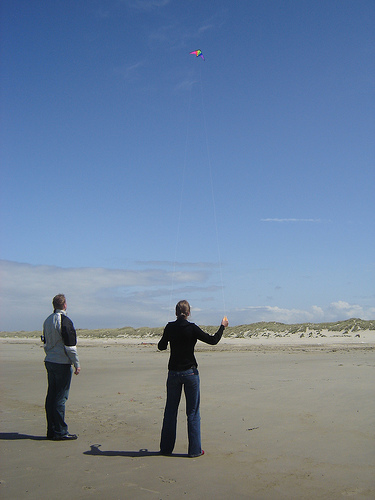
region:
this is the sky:
[43, 32, 104, 97]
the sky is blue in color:
[72, 163, 150, 204]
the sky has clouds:
[98, 264, 152, 309]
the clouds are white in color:
[102, 267, 144, 287]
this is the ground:
[278, 414, 326, 458]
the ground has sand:
[256, 432, 303, 457]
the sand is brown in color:
[251, 430, 296, 461]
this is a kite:
[188, 52, 212, 63]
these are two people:
[36, 291, 228, 467]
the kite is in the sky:
[163, 25, 246, 98]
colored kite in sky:
[191, 47, 205, 62]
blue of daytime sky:
[11, 3, 373, 260]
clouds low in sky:
[1, 257, 370, 328]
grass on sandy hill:
[1, 319, 372, 343]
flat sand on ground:
[0, 346, 373, 497]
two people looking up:
[42, 294, 226, 454]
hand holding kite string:
[194, 64, 227, 345]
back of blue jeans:
[159, 367, 200, 454]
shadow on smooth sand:
[84, 444, 193, 455]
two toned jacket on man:
[42, 310, 78, 365]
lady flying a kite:
[18, 13, 290, 472]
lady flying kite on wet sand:
[15, 45, 310, 469]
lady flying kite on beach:
[20, 38, 270, 480]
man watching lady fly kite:
[19, 34, 245, 462]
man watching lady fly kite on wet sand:
[24, 23, 242, 478]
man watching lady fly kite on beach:
[17, 18, 259, 461]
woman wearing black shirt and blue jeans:
[132, 280, 260, 461]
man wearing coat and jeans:
[38, 274, 110, 467]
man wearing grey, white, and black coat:
[27, 285, 98, 498]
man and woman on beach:
[18, 249, 257, 476]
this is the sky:
[25, 22, 108, 76]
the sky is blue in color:
[96, 131, 171, 188]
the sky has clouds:
[114, 110, 187, 157]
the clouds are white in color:
[150, 143, 222, 216]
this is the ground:
[246, 422, 310, 465]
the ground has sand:
[263, 399, 325, 462]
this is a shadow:
[81, 438, 156, 461]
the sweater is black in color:
[182, 330, 191, 340]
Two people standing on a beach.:
[34, 291, 231, 457]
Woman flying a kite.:
[155, 43, 231, 459]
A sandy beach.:
[3, 342, 369, 496]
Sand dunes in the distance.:
[1, 318, 372, 349]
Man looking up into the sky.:
[38, 292, 83, 441]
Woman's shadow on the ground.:
[82, 441, 159, 459]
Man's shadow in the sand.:
[1, 428, 45, 443]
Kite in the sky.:
[184, 46, 209, 64]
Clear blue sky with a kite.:
[2, 1, 367, 244]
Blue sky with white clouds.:
[2, 1, 372, 312]